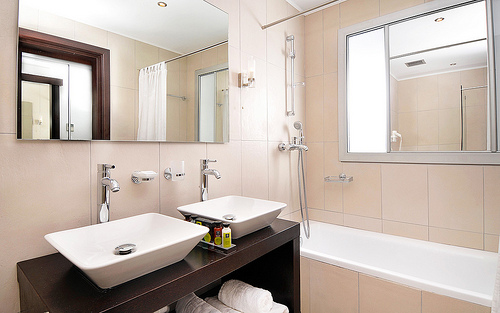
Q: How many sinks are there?
A: Two.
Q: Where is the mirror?
A: On the wall.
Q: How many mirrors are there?
A: 2.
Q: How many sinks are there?
A: 2.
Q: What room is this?
A: Bathroom.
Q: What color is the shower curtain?
A: White.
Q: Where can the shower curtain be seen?
A: As reflection in mirror.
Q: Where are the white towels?
A: On shelf under sinks.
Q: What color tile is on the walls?
A: Light pink.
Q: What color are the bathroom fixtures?
A: Silver.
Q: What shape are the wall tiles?
A: Square.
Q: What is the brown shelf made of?
A: Wood.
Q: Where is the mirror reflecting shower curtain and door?
A: Mirror on the sinks.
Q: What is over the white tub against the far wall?
A: Mirror to the right of the tub.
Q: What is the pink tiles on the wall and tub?
A: Bathroom with pink tiles.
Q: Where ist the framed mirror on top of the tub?
A: Bathroom over countertop.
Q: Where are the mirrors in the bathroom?
A: To the right and left.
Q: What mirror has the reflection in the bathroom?
A: The mirror to the left.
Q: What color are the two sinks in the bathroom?
A: The two sinks are white.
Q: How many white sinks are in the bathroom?
A: Two white sinks.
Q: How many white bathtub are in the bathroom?
A: One white bathtub.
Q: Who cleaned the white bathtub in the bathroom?
A: A person.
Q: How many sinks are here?
A: 2.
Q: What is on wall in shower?
A: Mirror.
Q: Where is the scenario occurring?
A: Bathroom.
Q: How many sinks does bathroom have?
A: 2.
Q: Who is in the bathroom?
A: No one.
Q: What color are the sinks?
A: White.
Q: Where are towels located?
A: Under sinks in vanity.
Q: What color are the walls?
A: Pink.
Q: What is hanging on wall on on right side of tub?
A: Mirror.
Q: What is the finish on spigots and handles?
A: Chrome.